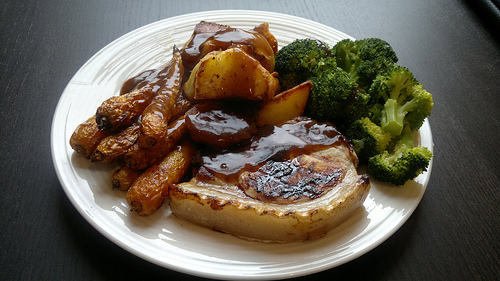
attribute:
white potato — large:
[253, 77, 314, 123]